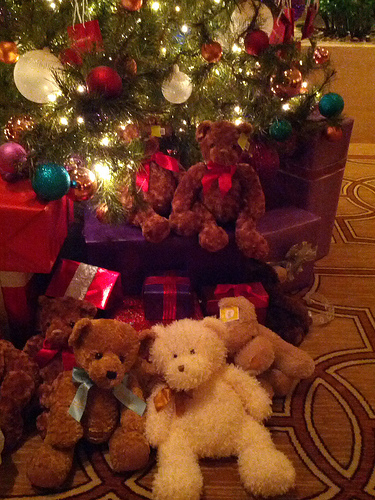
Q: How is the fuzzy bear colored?
A: White.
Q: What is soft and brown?
A: The teddy bear.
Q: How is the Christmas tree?
A: Decorated and lit up.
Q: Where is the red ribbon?
A: On the teddy bear.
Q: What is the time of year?
A: Christmas.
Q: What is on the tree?
A: Ornaments.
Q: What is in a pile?
A: Bears.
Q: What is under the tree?
A: Presents.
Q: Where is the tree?
A: Living room.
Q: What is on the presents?
A: Gift wrap.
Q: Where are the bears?
A: On carpet.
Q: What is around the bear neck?
A: Ribbon.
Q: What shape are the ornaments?
A: Round.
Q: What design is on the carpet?
A: Beige and red.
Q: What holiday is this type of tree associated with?
A: The tree is associated with Christmas.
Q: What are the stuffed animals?
A: The stuffed animals are bears.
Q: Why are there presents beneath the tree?
A: The presents are likely part of the Christmas holiday.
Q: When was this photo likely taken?
A: The photo was likely taken near Christmas.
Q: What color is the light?
A: The lights on the tree are white.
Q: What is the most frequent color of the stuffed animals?
A: The most frequently present color of stuffed animal is brown.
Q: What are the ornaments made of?
A: A few are made of glass, the others are likely metal.